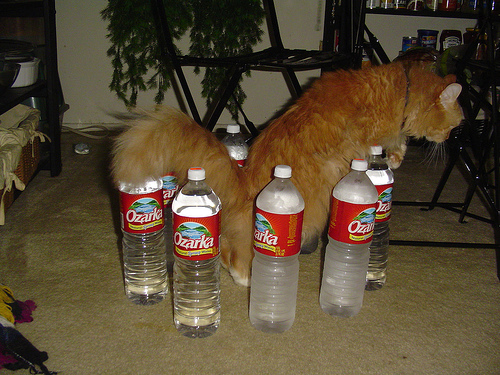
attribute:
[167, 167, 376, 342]
bottles — water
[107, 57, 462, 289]
fur — orange, long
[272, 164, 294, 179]
top — white, plastic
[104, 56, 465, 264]
cat — orange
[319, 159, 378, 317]
bottle — water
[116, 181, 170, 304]
bottle — water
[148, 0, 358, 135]
chair — Black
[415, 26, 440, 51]
container — plastic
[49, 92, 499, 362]
floor — Black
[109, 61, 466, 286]
cat — orange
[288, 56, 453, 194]
cat — orange, fluffy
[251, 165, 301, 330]
bottle — water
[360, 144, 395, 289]
bottle — water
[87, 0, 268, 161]
plant — Green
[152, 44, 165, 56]
leaf — green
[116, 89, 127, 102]
leaf — green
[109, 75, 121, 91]
leaf — green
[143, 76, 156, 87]
leaf — green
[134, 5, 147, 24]
leaf — green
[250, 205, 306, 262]
labels. — red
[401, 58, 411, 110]
collar — dark